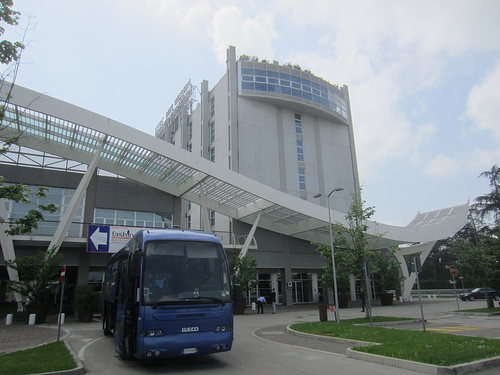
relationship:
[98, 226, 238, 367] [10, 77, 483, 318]
bus parked under ramp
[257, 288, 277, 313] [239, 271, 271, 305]
people standing in entryway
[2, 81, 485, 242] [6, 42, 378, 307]
ramp in front of building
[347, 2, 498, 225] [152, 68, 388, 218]
clouds behind building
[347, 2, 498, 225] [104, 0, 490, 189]
clouds in sky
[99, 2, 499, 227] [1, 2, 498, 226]
clouds in sky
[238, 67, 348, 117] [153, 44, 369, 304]
windows at top of building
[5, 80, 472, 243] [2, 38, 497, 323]
railing over side of building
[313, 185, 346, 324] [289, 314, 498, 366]
light pole in grass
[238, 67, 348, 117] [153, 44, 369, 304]
windows extending from building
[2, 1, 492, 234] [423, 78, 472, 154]
cloud in sky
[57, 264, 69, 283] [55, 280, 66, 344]
sign on pole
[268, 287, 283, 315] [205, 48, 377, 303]
person in front of building